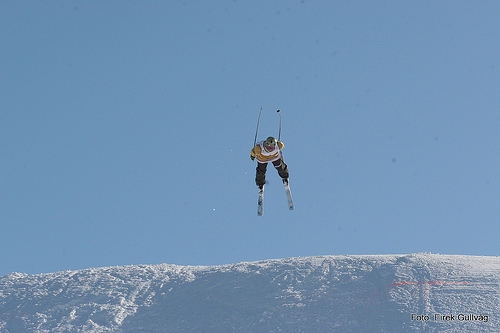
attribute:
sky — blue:
[0, 1, 499, 265]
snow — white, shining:
[0, 258, 499, 331]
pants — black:
[254, 159, 290, 182]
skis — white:
[257, 192, 303, 214]